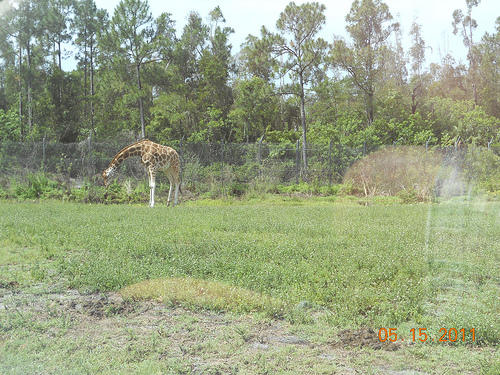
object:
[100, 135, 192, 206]
giraffe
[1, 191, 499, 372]
grass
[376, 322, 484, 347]
date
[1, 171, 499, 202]
grass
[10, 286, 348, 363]
dirt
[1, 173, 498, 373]
field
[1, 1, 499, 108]
sky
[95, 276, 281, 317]
reflection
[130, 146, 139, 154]
spot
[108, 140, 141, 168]
neck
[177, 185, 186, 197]
hair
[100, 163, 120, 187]
head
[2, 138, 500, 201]
fence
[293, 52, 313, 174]
trunk